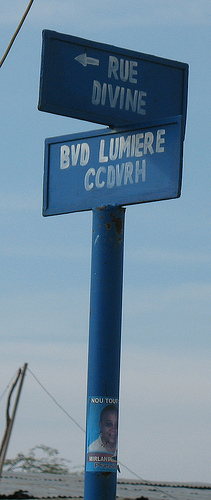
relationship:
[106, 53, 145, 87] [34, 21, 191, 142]
rue on sign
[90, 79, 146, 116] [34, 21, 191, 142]
divine on sign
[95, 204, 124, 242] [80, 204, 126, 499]
rusty area on pole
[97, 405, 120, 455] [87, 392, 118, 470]
person on paper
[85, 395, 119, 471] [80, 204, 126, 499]
picture on pole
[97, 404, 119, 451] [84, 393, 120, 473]
woman on picture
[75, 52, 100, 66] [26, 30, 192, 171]
arrow on sign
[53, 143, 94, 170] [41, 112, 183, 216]
bvd on sign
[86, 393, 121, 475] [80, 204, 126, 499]
paper on pole